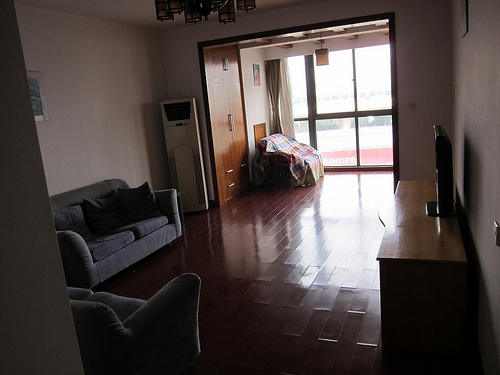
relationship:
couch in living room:
[43, 174, 185, 279] [10, 6, 483, 366]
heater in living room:
[156, 89, 231, 224] [10, 6, 483, 366]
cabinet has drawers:
[373, 165, 485, 362] [389, 207, 404, 355]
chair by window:
[251, 126, 327, 197] [248, 47, 404, 186]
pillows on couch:
[79, 175, 161, 234] [43, 174, 185, 279]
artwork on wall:
[19, 68, 59, 131] [13, 0, 197, 206]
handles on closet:
[227, 115, 236, 137] [201, 47, 262, 199]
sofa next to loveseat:
[43, 174, 185, 279] [64, 264, 201, 374]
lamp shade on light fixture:
[202, 6, 209, 13] [149, 4, 259, 36]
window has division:
[248, 47, 404, 186] [302, 51, 324, 163]